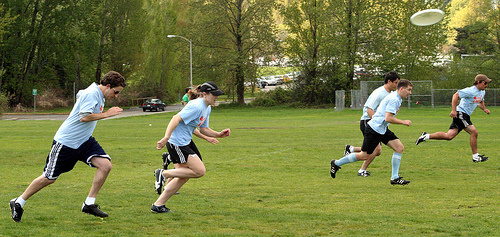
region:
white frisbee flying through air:
[408, 5, 448, 27]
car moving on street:
[138, 94, 165, 112]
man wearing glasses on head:
[5, 67, 126, 224]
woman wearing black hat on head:
[147, 75, 229, 215]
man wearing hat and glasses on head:
[411, 70, 491, 165]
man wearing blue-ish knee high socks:
[328, 78, 413, 185]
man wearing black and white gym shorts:
[8, 68, 129, 225]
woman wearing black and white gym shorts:
[151, 82, 232, 214]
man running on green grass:
[329, 78, 414, 185]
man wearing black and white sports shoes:
[416, 73, 494, 162]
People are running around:
[18, 20, 490, 232]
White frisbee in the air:
[397, 6, 459, 45]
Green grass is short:
[245, 168, 312, 218]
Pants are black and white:
[156, 136, 196, 167]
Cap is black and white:
[191, 75, 226, 95]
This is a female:
[141, 60, 231, 235]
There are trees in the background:
[10, 0, 495, 135]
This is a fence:
[320, 50, 443, 130]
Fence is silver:
[327, 62, 433, 117]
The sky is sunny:
[15, 7, 498, 131]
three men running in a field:
[357, 58, 490, 194]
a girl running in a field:
[157, 77, 228, 206]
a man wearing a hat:
[466, 61, 493, 90]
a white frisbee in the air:
[402, 4, 461, 38]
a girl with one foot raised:
[145, 141, 206, 194]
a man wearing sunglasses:
[102, 71, 122, 110]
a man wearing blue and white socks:
[328, 149, 361, 174]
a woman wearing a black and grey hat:
[189, 72, 229, 104]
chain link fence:
[405, 71, 440, 128]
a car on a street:
[134, 86, 179, 128]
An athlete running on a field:
[6, 68, 126, 225]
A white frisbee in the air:
[408, 5, 447, 30]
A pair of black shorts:
[40, 134, 113, 182]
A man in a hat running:
[413, 71, 496, 165]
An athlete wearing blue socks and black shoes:
[325, 148, 412, 188]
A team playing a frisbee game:
[6, 4, 495, 223]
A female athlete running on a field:
[145, 80, 232, 214]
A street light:
[163, 31, 196, 101]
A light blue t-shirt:
[50, 78, 107, 151]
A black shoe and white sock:
[78, 192, 110, 219]